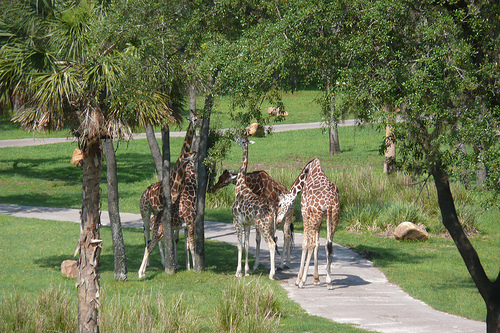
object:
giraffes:
[137, 109, 340, 289]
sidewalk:
[0, 204, 486, 333]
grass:
[0, 213, 377, 332]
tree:
[77, 0, 212, 276]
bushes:
[376, 198, 427, 231]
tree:
[0, 1, 177, 332]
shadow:
[0, 152, 176, 215]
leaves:
[209, 167, 213, 173]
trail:
[0, 112, 487, 332]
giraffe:
[138, 109, 208, 278]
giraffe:
[233, 129, 281, 280]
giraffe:
[275, 157, 341, 290]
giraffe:
[206, 169, 295, 271]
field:
[0, 90, 500, 333]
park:
[0, 0, 500, 333]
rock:
[393, 221, 430, 242]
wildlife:
[138, 108, 341, 290]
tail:
[325, 205, 333, 256]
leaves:
[399, 55, 404, 60]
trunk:
[382, 105, 399, 173]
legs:
[324, 200, 340, 290]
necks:
[235, 147, 249, 193]